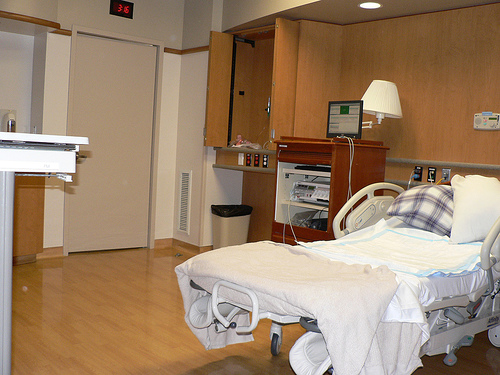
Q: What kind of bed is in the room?
A: Hospital.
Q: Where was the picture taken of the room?
A: In a hospital.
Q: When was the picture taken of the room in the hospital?
A: Day of patient's release.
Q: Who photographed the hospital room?
A: A patient.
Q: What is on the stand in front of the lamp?
A: Monitor.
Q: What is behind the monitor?
A: A white lamp.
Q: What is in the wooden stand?
A: Medical equipment.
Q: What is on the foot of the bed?
A: A blanket.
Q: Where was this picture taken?
A: In a hospital room.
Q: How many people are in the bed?
A: None.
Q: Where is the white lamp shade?
A: Behind the computer screen.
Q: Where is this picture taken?
A: A hospital room.